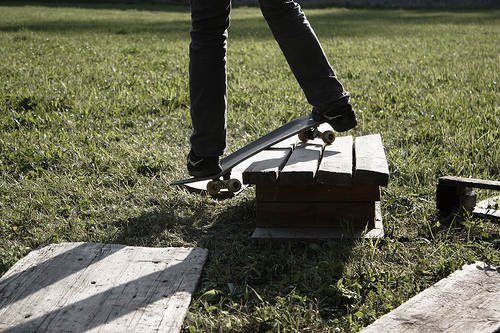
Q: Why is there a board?
A: Skating.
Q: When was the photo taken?
A: Daytime.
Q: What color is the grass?
A: Green.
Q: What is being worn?
A: Shoes.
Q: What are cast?
A: Shadows.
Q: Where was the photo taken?
A: At a park.